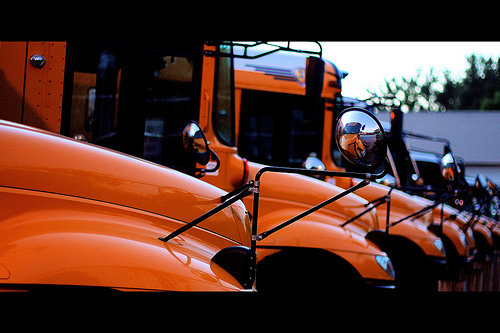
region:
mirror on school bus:
[148, 108, 220, 173]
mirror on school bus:
[335, 109, 381, 167]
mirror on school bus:
[433, 153, 452, 195]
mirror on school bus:
[466, 165, 492, 206]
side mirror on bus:
[177, 129, 212, 173]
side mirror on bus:
[433, 147, 458, 187]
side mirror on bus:
[471, 173, 491, 211]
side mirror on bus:
[337, 118, 396, 180]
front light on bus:
[367, 252, 396, 307]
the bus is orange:
[28, 139, 247, 311]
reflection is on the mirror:
[329, 108, 379, 174]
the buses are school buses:
[1, 30, 496, 302]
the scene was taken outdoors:
[8, 40, 495, 301]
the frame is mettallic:
[251, 170, 313, 245]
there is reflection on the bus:
[87, 171, 232, 248]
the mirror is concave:
[312, 108, 394, 170]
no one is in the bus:
[91, 48, 194, 162]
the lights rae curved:
[371, 236, 403, 283]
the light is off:
[372, 250, 399, 275]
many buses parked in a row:
[2, 38, 496, 309]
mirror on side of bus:
[176, 118, 216, 166]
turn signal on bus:
[236, 155, 253, 185]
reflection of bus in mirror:
[327, 108, 370, 161]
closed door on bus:
[238, 85, 322, 167]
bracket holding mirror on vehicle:
[167, 157, 379, 274]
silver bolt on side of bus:
[28, 53, 47, 67]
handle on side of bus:
[201, 88, 216, 133]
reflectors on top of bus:
[250, 63, 297, 83]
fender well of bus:
[254, 225, 402, 290]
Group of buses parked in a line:
[54, 70, 474, 315]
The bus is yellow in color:
[37, 133, 222, 294]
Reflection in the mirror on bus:
[331, 69, 398, 190]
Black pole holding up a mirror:
[193, 137, 309, 236]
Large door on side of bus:
[64, 60, 254, 187]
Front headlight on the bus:
[356, 243, 426, 314]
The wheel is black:
[261, 256, 377, 326]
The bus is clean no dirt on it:
[31, 170, 161, 290]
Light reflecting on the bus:
[165, 230, 221, 286]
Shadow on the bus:
[276, 233, 426, 278]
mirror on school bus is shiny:
[315, 87, 385, 173]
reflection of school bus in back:
[347, 124, 369, 169]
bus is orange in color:
[0, 149, 203, 289]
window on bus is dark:
[237, 97, 319, 163]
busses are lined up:
[12, 80, 498, 283]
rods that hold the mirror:
[167, 174, 365, 240]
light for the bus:
[375, 240, 395, 305]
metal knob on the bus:
[30, 47, 46, 76]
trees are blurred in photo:
[344, 89, 484, 116]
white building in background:
[408, 97, 494, 154]